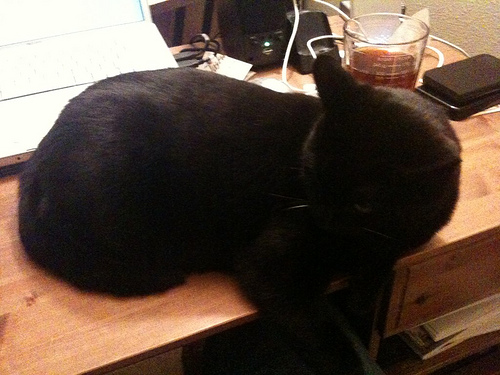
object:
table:
[1, 256, 499, 363]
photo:
[29, 17, 479, 355]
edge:
[95, 338, 235, 357]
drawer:
[399, 231, 499, 326]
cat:
[18, 55, 461, 373]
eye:
[348, 193, 382, 217]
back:
[86, 84, 320, 187]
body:
[71, 113, 260, 263]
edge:
[385, 269, 410, 338]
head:
[297, 112, 471, 240]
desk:
[2, 230, 499, 345]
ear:
[310, 48, 352, 109]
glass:
[342, 16, 431, 87]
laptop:
[9, 20, 158, 101]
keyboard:
[13, 48, 130, 78]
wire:
[294, 10, 342, 68]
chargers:
[245, 14, 334, 61]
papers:
[210, 48, 306, 99]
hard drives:
[418, 53, 499, 121]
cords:
[274, 4, 464, 63]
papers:
[409, 297, 498, 358]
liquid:
[356, 55, 405, 83]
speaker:
[237, 7, 290, 76]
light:
[259, 37, 271, 50]